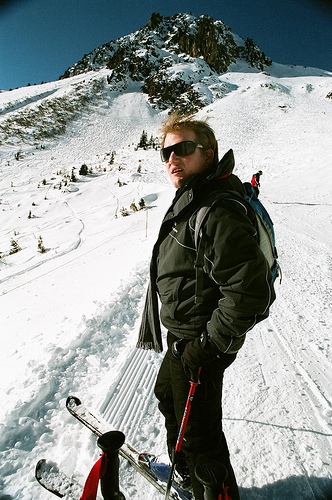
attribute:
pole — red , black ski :
[136, 345, 203, 496]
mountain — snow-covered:
[2, 3, 331, 498]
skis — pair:
[35, 392, 185, 497]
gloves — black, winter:
[180, 335, 234, 393]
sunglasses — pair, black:
[160, 138, 207, 160]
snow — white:
[18, 87, 298, 424]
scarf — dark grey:
[136, 186, 176, 353]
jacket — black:
[159, 153, 276, 359]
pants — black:
[159, 334, 241, 492]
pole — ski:
[164, 350, 205, 496]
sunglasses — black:
[160, 138, 213, 163]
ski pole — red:
[163, 364, 201, 499]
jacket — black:
[146, 174, 283, 357]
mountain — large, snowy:
[0, 3, 330, 123]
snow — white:
[70, 191, 109, 257]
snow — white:
[52, 253, 131, 344]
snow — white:
[14, 304, 73, 370]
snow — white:
[245, 339, 324, 415]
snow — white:
[219, 325, 319, 438]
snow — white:
[277, 226, 330, 285]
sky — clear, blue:
[19, 12, 61, 77]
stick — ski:
[164, 376, 200, 496]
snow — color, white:
[45, 280, 122, 355]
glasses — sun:
[156, 138, 201, 160]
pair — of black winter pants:
[154, 328, 242, 493]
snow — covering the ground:
[22, 255, 120, 370]